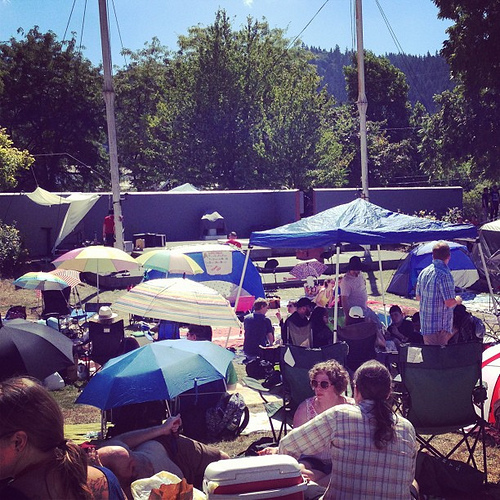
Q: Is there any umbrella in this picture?
A: Yes, there is an umbrella.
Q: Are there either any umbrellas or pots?
A: Yes, there is an umbrella.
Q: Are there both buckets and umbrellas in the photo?
A: No, there is an umbrella but no buckets.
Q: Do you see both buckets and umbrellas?
A: No, there is an umbrella but no buckets.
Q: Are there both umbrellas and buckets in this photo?
A: No, there is an umbrella but no buckets.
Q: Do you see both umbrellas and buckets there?
A: No, there is an umbrella but no buckets.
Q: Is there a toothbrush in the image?
A: No, there are no toothbrushes.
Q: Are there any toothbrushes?
A: No, there are no toothbrushes.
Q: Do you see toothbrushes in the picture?
A: No, there are no toothbrushes.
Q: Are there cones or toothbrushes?
A: No, there are no toothbrushes or cones.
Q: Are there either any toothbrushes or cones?
A: No, there are no toothbrushes or cones.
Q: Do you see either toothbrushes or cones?
A: No, there are no toothbrushes or cones.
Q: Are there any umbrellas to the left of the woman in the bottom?
A: Yes, there is an umbrella to the left of the woman.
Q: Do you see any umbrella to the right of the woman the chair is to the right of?
A: No, the umbrella is to the left of the woman.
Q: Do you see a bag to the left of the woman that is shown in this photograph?
A: No, there is an umbrella to the left of the woman.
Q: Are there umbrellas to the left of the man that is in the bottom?
A: Yes, there is an umbrella to the left of the man.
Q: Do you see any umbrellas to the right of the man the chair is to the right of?
A: No, the umbrella is to the left of the man.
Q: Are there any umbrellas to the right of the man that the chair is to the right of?
A: No, the umbrella is to the left of the man.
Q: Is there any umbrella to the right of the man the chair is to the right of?
A: No, the umbrella is to the left of the man.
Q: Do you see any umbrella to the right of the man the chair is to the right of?
A: No, the umbrella is to the left of the man.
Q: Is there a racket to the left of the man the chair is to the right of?
A: No, there is an umbrella to the left of the man.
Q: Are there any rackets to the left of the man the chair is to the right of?
A: No, there is an umbrella to the left of the man.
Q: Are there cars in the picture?
A: No, there are no cars.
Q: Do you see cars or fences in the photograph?
A: No, there are no cars or fences.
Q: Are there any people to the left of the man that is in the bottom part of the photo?
A: Yes, there is a person to the left of the man.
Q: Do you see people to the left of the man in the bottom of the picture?
A: Yes, there is a person to the left of the man.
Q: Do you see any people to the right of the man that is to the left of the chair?
A: No, the person is to the left of the man.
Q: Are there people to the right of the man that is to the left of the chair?
A: No, the person is to the left of the man.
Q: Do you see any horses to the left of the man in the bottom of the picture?
A: No, there is a person to the left of the man.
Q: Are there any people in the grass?
A: Yes, there is a person in the grass.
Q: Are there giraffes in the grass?
A: No, there is a person in the grass.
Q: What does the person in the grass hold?
A: The person holds the umbrella.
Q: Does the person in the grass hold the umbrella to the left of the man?
A: Yes, the person holds the umbrella.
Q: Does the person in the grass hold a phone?
A: No, the person holds the umbrella.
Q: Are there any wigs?
A: No, there are no wigs.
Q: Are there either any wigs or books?
A: No, there are no wigs or books.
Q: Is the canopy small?
A: Yes, the canopy is small.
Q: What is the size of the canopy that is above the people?
A: The canopy is small.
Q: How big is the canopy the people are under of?
A: The canopy is small.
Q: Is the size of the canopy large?
A: No, the canopy is small.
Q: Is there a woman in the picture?
A: Yes, there is a woman.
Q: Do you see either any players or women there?
A: Yes, there is a woman.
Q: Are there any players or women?
A: Yes, there is a woman.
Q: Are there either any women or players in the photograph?
A: Yes, there is a woman.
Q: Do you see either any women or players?
A: Yes, there is a woman.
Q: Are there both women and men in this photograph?
A: Yes, there are both a woman and a man.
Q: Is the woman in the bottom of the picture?
A: Yes, the woman is in the bottom of the image.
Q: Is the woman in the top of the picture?
A: No, the woman is in the bottom of the image.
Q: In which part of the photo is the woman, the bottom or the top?
A: The woman is in the bottom of the image.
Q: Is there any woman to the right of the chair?
A: No, the woman is to the left of the chair.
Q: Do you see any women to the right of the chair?
A: No, the woman is to the left of the chair.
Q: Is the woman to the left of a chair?
A: Yes, the woman is to the left of a chair.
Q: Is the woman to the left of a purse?
A: No, the woman is to the left of a chair.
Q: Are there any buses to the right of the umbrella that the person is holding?
A: No, there is a woman to the right of the umbrella.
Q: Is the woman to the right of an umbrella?
A: Yes, the woman is to the right of an umbrella.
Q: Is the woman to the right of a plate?
A: No, the woman is to the right of an umbrella.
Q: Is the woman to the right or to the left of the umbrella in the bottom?
A: The woman is to the right of the umbrella.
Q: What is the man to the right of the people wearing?
A: The man is wearing a shirt.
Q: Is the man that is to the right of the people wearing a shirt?
A: Yes, the man is wearing a shirt.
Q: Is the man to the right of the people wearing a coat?
A: No, the man is wearing a shirt.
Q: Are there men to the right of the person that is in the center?
A: Yes, there is a man to the right of the person.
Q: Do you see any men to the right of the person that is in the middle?
A: Yes, there is a man to the right of the person.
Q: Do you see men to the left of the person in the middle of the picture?
A: No, the man is to the right of the person.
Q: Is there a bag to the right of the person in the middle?
A: No, there is a man to the right of the person.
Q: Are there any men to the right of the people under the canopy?
A: Yes, there is a man to the right of the people.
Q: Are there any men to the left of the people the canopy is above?
A: No, the man is to the right of the people.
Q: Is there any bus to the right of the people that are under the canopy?
A: No, there is a man to the right of the people.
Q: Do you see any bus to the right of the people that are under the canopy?
A: No, there is a man to the right of the people.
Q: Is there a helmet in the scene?
A: No, there are no helmets.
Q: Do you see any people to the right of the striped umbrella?
A: Yes, there is a person to the right of the umbrella.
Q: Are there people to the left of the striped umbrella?
A: No, the person is to the right of the umbrella.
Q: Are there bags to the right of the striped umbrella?
A: No, there is a person to the right of the umbrella.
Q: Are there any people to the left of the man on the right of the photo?
A: Yes, there is a person to the left of the man.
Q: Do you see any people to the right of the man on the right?
A: No, the person is to the left of the man.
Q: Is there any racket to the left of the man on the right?
A: No, there is a person to the left of the man.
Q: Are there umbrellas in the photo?
A: Yes, there is an umbrella.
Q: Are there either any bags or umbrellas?
A: Yes, there is an umbrella.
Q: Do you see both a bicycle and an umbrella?
A: No, there is an umbrella but no bicycles.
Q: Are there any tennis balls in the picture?
A: No, there are no tennis balls.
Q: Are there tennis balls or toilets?
A: No, there are no tennis balls or toilets.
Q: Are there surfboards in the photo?
A: No, there are no surfboards.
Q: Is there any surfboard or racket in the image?
A: No, there are no surfboards or rackets.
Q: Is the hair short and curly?
A: Yes, the hair is short and curly.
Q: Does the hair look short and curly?
A: Yes, the hair is short and curly.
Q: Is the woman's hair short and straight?
A: No, the hair is short but curly.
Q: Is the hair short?
A: Yes, the hair is short.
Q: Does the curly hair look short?
A: Yes, the hair is short.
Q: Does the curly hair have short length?
A: Yes, the hair is short.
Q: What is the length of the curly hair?
A: The hair is short.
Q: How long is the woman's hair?
A: The hair is short.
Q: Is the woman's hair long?
A: No, the hair is short.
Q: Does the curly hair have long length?
A: No, the hair is short.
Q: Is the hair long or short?
A: The hair is short.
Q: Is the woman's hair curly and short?
A: Yes, the hair is curly and short.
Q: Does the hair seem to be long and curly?
A: No, the hair is curly but short.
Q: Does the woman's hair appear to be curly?
A: Yes, the hair is curly.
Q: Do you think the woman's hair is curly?
A: Yes, the hair is curly.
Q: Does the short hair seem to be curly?
A: Yes, the hair is curly.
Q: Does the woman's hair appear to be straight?
A: No, the hair is curly.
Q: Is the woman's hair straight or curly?
A: The hair is curly.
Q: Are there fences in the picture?
A: No, there are no fences.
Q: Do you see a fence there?
A: No, there are no fences.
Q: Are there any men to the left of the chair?
A: Yes, there is a man to the left of the chair.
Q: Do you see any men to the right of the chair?
A: No, the man is to the left of the chair.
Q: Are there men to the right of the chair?
A: No, the man is to the left of the chair.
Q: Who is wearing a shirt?
A: The man is wearing a shirt.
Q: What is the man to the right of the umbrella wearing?
A: The man is wearing a shirt.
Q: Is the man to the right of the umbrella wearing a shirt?
A: Yes, the man is wearing a shirt.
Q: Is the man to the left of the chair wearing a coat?
A: No, the man is wearing a shirt.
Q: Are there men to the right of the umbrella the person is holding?
A: Yes, there is a man to the right of the umbrella.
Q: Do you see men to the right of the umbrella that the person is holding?
A: Yes, there is a man to the right of the umbrella.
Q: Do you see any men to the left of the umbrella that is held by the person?
A: No, the man is to the right of the umbrella.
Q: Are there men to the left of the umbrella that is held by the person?
A: No, the man is to the right of the umbrella.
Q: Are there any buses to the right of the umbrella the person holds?
A: No, there is a man to the right of the umbrella.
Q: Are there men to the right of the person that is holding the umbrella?
A: Yes, there is a man to the right of the person.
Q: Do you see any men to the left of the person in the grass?
A: No, the man is to the right of the person.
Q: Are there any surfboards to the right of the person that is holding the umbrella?
A: No, there is a man to the right of the person.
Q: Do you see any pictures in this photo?
A: No, there are no pictures.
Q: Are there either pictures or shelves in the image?
A: No, there are no pictures or shelves.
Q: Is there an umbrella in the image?
A: Yes, there is an umbrella.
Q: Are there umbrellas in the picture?
A: Yes, there is an umbrella.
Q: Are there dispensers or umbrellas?
A: Yes, there is an umbrella.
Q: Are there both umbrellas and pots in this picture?
A: No, there is an umbrella but no pots.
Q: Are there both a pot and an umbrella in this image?
A: No, there is an umbrella but no pots.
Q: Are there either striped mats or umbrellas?
A: Yes, there is a striped umbrella.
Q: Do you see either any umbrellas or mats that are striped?
A: Yes, the umbrella is striped.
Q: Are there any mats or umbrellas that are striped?
A: Yes, the umbrella is striped.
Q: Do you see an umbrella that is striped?
A: Yes, there is a striped umbrella.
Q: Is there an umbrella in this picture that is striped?
A: Yes, there is an umbrella that is striped.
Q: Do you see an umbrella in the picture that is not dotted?
A: Yes, there is a striped umbrella.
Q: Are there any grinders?
A: No, there are no grinders.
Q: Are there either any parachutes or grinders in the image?
A: No, there are no grinders or parachutes.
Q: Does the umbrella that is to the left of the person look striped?
A: Yes, the umbrella is striped.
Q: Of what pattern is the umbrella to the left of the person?
A: The umbrella is striped.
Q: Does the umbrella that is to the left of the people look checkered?
A: No, the umbrella is striped.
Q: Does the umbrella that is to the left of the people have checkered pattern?
A: No, the umbrella is striped.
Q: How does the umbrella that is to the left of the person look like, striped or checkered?
A: The umbrella is striped.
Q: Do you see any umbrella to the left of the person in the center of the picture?
A: Yes, there is an umbrella to the left of the person.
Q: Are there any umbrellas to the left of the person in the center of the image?
A: Yes, there is an umbrella to the left of the person.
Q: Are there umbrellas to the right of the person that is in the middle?
A: No, the umbrella is to the left of the person.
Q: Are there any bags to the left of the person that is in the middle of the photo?
A: No, there is an umbrella to the left of the person.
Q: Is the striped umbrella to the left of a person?
A: Yes, the umbrella is to the left of a person.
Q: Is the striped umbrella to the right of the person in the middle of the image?
A: No, the umbrella is to the left of the person.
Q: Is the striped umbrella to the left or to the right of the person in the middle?
A: The umbrella is to the left of the person.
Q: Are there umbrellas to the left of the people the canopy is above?
A: Yes, there is an umbrella to the left of the people.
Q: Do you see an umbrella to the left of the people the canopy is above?
A: Yes, there is an umbrella to the left of the people.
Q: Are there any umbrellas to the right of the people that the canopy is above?
A: No, the umbrella is to the left of the people.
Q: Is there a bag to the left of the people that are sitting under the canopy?
A: No, there is an umbrella to the left of the people.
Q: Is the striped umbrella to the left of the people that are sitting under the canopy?
A: Yes, the umbrella is to the left of the people.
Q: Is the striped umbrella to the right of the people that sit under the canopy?
A: No, the umbrella is to the left of the people.